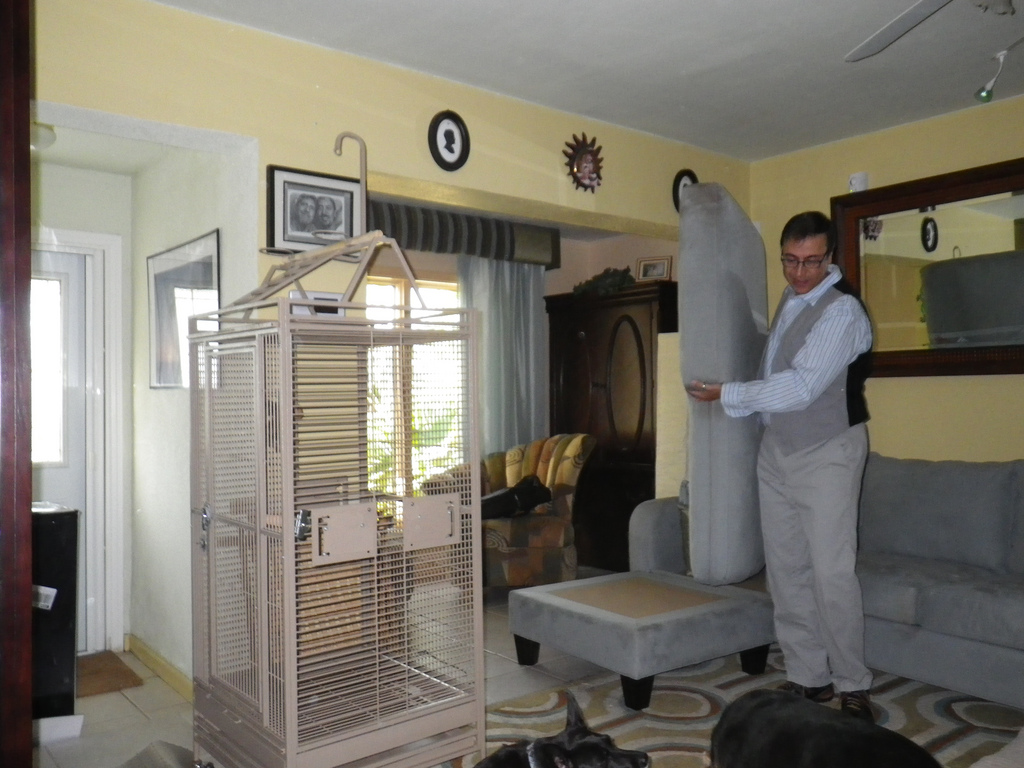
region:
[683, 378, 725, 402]
A man's left hand.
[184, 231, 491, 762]
A tall cream colored bird cage.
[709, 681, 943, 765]
A bigger black dog.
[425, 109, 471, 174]
A black oval picture with silhouette of a head in it.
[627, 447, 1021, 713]
A long grey couch.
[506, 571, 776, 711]
Grey ottoman with black legs and no cushion.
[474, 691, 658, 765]
Black dog with collar on.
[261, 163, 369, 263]
Black framed photo above a cage.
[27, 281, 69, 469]
a window on a building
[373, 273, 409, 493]
a window on a building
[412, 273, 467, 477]
a window on a building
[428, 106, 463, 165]
a picture in a frame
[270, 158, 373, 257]
a picture in a frame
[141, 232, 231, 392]
a picture in a frame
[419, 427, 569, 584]
a chair that you sit in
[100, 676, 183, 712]
a tile in a floor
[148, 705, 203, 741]
a tile in a floor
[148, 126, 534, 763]
A light brown tall birdcage.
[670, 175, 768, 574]
A sofa cushion.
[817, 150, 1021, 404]
A wooden framed mirror.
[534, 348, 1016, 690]
A light gray sofa.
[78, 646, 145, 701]
A door mat.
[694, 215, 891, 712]
A man wearing glasses.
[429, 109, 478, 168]
A round black framed picture of a head.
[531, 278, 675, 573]
A wooden cabinet.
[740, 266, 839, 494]
man has grey vest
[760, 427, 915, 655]
man has grey pants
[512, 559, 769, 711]
grey and brown footrest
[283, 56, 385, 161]
wall is matte yellow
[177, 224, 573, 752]
tan bird cage in the room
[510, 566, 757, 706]
ottoman missing the cushion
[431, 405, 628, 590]
multi color chair near the window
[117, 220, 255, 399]
piucture hanging on the white wall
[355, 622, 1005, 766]
rug with circles on it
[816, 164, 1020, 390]
mirror on the yellow wall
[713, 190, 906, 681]
man holding the cushion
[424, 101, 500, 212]
picture with a profile of someone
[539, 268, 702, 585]
brown armoir in the other room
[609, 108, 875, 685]
A man holding a couch cushion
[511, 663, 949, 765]
two dogs playing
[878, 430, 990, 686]
A gray couch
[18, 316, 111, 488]
A white door with a window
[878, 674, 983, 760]
A brown rug on the floor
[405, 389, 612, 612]
A brown chair by the window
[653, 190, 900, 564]
A man was a blue and white shirt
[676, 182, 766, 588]
Long grey couch cushion a man is holding.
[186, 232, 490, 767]
A cream colored bird cage.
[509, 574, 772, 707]
Ottoman with black legs and no cushion.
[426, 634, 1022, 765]
A white, brown and tan area rug.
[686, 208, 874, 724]
Dark haired man with glasses.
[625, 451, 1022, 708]
A grey couch missing a cushion.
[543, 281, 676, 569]
A dark cabinet over by a curtain.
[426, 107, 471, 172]
Oval black frame on the wall with a silhouette inside.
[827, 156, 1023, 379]
A thick dark framed mirror.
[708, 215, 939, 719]
Man with dark hair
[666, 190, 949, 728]
Man wearing a vest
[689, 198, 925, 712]
Man in black shoes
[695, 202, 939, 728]
Man wearing black glasses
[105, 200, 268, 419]
framed picture on wall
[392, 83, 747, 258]
framed pictures on wall